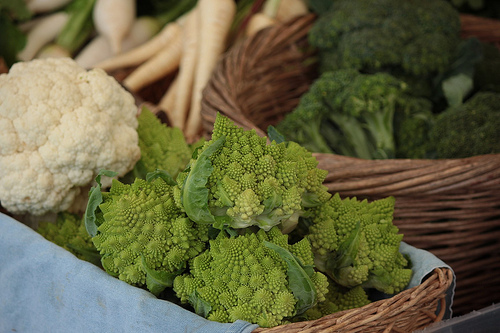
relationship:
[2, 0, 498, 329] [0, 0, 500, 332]
many different items are in photo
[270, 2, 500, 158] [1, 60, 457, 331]
broccoli in basket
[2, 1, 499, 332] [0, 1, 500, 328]
two baskets are full of vegetables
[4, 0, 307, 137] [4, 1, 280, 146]
turnips are in basket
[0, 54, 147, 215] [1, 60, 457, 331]
cauliflower in basket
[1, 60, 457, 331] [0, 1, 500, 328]
basket full of vegetables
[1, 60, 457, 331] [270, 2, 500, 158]
basket contains broccoli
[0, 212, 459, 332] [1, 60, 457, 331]
cloth on side of basket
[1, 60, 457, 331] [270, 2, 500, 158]
basket holding food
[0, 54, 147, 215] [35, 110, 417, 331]
cauliflower next to vegetables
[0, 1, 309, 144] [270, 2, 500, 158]
rutabega near broccoli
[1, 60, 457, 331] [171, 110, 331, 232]
basket with stuff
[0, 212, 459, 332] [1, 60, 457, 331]
cloth hanging from basket